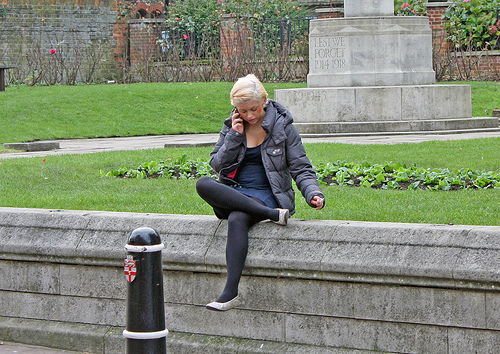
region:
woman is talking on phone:
[197, 72, 325, 314]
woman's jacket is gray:
[205, 98, 325, 208]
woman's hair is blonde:
[226, 70, 268, 105]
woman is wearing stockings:
[195, 175, 275, 300]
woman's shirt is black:
[240, 140, 275, 187]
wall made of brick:
[111, 0, 496, 85]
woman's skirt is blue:
[235, 177, 270, 207]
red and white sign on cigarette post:
[123, 257, 138, 284]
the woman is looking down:
[193, 72, 331, 314]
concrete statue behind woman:
[273, 2, 497, 130]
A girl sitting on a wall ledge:
[132, 25, 367, 307]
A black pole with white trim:
[111, 195, 186, 347]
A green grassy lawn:
[44, 87, 184, 194]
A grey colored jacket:
[268, 112, 309, 198]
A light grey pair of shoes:
[207, 200, 287, 332]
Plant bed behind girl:
[323, 148, 480, 203]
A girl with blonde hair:
[221, 63, 278, 117]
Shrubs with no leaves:
[36, 22, 260, 74]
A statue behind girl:
[294, 8, 437, 111]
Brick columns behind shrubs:
[122, 5, 306, 60]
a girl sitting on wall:
[164, 47, 349, 310]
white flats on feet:
[190, 269, 290, 341]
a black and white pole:
[101, 210, 175, 352]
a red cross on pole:
[110, 252, 147, 300]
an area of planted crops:
[120, 133, 499, 238]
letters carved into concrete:
[297, 27, 364, 82]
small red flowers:
[150, 13, 203, 48]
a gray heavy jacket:
[188, 74, 340, 245]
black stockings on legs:
[193, 176, 291, 306]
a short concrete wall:
[11, 188, 496, 353]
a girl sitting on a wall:
[171, 40, 361, 352]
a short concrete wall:
[7, 196, 497, 352]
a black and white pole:
[81, 215, 201, 352]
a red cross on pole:
[108, 256, 154, 283]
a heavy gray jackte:
[200, 86, 347, 236]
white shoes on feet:
[190, 279, 285, 323]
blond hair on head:
[213, 70, 273, 113]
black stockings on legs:
[190, 169, 293, 299]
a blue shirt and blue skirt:
[233, 135, 293, 228]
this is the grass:
[62, 162, 101, 198]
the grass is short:
[361, 197, 387, 210]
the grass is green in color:
[352, 189, 384, 212]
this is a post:
[105, 230, 184, 352]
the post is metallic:
[118, 239, 170, 350]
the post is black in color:
[131, 294, 160, 321]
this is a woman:
[187, 72, 327, 314]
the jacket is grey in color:
[283, 149, 308, 179]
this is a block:
[309, 22, 451, 117]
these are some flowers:
[165, 12, 210, 62]